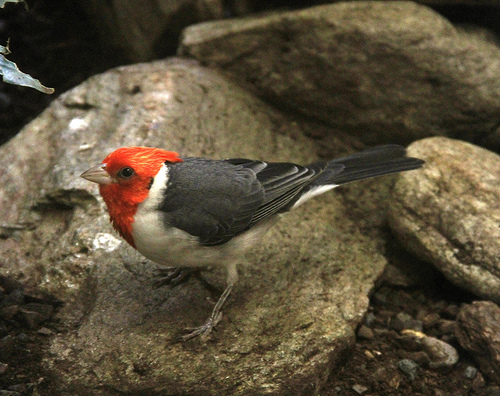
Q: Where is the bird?
A: On the rock.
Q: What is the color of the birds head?
A: Red.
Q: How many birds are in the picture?
A: One.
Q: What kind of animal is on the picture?
A: A bird.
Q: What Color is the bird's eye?
A: Black.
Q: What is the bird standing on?
A: A rock.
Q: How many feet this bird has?
A: Two.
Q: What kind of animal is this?
A: Bird.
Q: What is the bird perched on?
A: A rock.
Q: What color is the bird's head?
A: Red.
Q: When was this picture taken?
A: Daytime.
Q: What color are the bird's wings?
A: Black.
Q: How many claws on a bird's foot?
A: Four.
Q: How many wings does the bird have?
A: Two.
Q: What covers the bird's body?
A: Feathers.